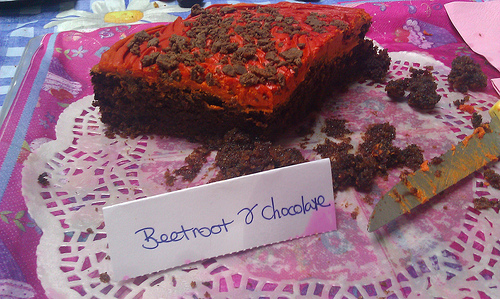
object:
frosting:
[360, 104, 499, 232]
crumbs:
[460, 126, 485, 147]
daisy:
[43, 0, 193, 34]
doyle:
[21, 35, 499, 298]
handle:
[488, 97, 500, 122]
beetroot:
[136, 213, 233, 250]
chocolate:
[260, 188, 332, 224]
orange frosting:
[92, 2, 365, 111]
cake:
[89, 0, 371, 139]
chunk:
[279, 45, 302, 60]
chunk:
[125, 39, 142, 57]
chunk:
[137, 52, 155, 65]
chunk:
[145, 36, 157, 47]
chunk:
[257, 36, 271, 45]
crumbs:
[456, 102, 478, 116]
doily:
[21, 35, 498, 297]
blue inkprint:
[133, 194, 330, 261]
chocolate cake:
[83, 1, 382, 151]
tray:
[0, 0, 500, 297]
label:
[100, 154, 338, 283]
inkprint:
[233, 201, 260, 226]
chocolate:
[139, 49, 159, 68]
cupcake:
[445, 55, 492, 92]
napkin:
[443, 0, 497, 70]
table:
[0, 0, 500, 297]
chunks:
[382, 78, 409, 101]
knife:
[361, 105, 499, 241]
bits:
[155, 33, 294, 69]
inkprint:
[260, 192, 333, 222]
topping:
[124, 25, 254, 70]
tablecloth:
[0, 0, 89, 299]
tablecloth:
[374, 0, 500, 65]